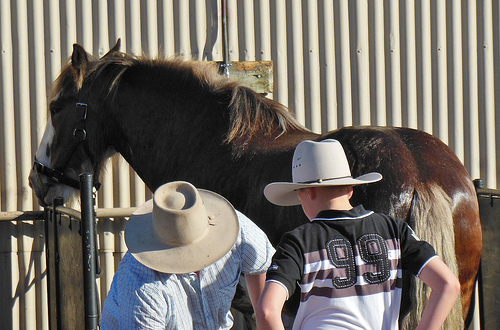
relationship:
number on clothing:
[327, 239, 357, 288] [267, 204, 438, 329]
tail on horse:
[399, 178, 466, 328] [20, 58, 480, 330]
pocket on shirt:
[217, 262, 243, 309] [99, 207, 276, 329]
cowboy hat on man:
[119, 177, 241, 277] [99, 181, 276, 329]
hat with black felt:
[252, 137, 390, 204] [298, 176, 352, 184]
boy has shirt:
[255, 139, 460, 328] [263, 204, 448, 326]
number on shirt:
[320, 230, 392, 297] [263, 204, 448, 326]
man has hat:
[99, 181, 276, 329] [116, 178, 242, 285]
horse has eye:
[20, 58, 480, 330] [39, 89, 71, 122]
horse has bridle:
[20, 58, 480, 330] [36, 82, 101, 189]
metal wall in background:
[0, 0, 499, 209] [4, 3, 484, 329]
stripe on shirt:
[417, 254, 437, 279] [255, 206, 430, 328]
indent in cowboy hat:
[154, 180, 196, 211] [124, 180, 241, 273]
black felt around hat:
[295, 177, 322, 184] [261, 137, 382, 207]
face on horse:
[29, 97, 70, 208] [20, 58, 480, 330]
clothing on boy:
[267, 204, 438, 329] [203, 115, 452, 305]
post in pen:
[78, 170, 99, 327] [3, 5, 498, 325]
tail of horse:
[412, 182, 468, 330] [28, 38, 481, 330]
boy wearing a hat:
[255, 139, 460, 328] [261, 137, 382, 207]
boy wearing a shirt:
[255, 139, 460, 328] [301, 205, 395, 315]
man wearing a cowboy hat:
[99, 181, 276, 329] [124, 180, 241, 273]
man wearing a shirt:
[74, 171, 295, 328] [99, 207, 276, 329]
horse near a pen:
[28, 38, 481, 330] [0, 178, 499, 329]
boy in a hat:
[255, 139, 460, 328] [261, 137, 382, 207]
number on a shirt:
[326, 231, 391, 288] [283, 211, 428, 316]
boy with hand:
[281, 154, 375, 250] [259, 301, 288, 328]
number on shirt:
[326, 231, 391, 288] [263, 204, 448, 326]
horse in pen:
[20, 58, 480, 330] [1, 113, 491, 330]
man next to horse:
[99, 181, 276, 329] [52, 61, 246, 171]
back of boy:
[331, 298, 358, 329] [264, 130, 469, 330]